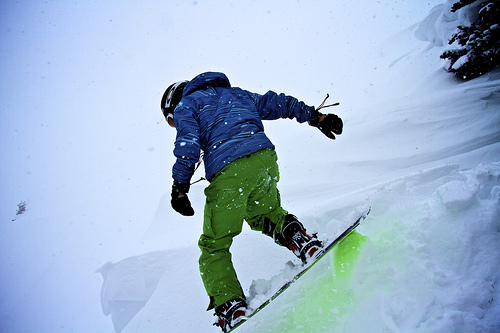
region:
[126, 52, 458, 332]
Person on a snowboard.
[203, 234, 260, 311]
Snow boot on the man.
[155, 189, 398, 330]
Snowboard on the snow.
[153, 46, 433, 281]
Man with a helmet.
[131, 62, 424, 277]
man wearing a pair of gloves.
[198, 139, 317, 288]
Green pants on the man.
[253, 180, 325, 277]
Red and white boots.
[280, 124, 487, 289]
Snow on the ground.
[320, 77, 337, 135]
Strings on the gloves.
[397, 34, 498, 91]
Tree on the ground.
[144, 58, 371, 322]
a skier on the snow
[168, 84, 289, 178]
blue snow coat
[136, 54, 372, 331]
skier wears green pants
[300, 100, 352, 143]
glove on right side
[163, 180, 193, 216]
glove on left side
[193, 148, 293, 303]
green snow pants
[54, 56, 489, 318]
skier on a slope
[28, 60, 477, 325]
skier going down the hill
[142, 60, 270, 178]
skier wears a helmet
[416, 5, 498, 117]
a tree on side a hill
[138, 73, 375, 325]
snowboarder going down mountain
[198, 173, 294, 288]
green pants of snowboarder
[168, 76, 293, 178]
blue coat of snowboarder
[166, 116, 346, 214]
black gloves of snowboarder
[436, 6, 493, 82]
tree with snow covered limbs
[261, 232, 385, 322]
green reflection on snow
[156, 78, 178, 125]
white snow goggles of skier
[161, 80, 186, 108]
black helmet of snowboarder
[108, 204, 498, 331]
snow snowboarder is boarding on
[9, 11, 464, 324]
sky behind snowboarder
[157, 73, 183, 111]
Black and white ski helmet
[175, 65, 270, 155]
Ocean and light blue colored jacket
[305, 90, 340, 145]
Black snow gloves with two strings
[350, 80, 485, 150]
White untouched snow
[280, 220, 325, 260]
Red, black and white ski boots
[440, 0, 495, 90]
Green pine tree with snowy limbs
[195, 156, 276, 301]
Green snow pants with a side pocket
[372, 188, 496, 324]
disturbed snow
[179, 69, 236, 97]
Jacket hood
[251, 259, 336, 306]
snow board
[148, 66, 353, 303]
young person riding snow board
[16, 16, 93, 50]
white clouds against blue sky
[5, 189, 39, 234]
bird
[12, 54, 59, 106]
white clouds against blue sky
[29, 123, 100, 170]
white clouds against blue sky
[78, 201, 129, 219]
white clouds against blue sky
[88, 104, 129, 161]
white clouds against blue sky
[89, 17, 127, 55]
white clouds against blue sky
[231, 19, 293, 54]
white clouds against blue sky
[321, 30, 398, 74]
white clouds against blue sky